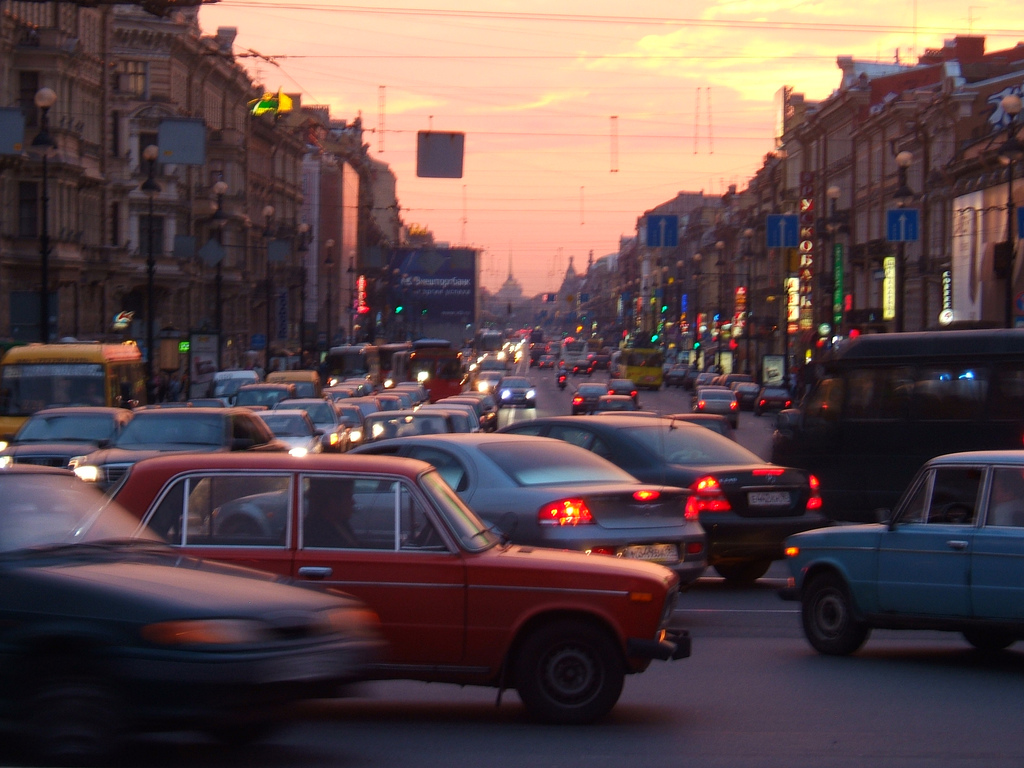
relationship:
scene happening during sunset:
[5, 3, 993, 760] [197, 5, 993, 289]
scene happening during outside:
[5, 3, 993, 760] [3, 3, 993, 758]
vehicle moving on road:
[70, 444, 695, 721] [5, 325, 993, 762]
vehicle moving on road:
[199, 424, 711, 595] [5, 325, 993, 762]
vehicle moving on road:
[495, 407, 828, 589] [5, 325, 993, 762]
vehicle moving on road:
[61, 400, 290, 504] [5, 325, 993, 762]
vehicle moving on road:
[247, 402, 328, 457] [5, 325, 993, 762]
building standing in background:
[3, 5, 312, 397] [1, 3, 989, 392]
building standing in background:
[294, 154, 362, 356] [1, 3, 989, 392]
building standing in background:
[301, 100, 405, 343] [1, 3, 989, 392]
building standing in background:
[770, 27, 993, 343] [1, 3, 989, 392]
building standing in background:
[636, 178, 738, 356] [1, 3, 989, 392]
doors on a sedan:
[136, 476, 467, 656] [58, 450, 692, 721]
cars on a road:
[30, 320, 1022, 763] [5, 325, 993, 762]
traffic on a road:
[0, 318, 1016, 748] [5, 325, 993, 762]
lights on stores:
[613, 249, 953, 377] [592, 201, 971, 411]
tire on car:
[505, 610, 629, 721] [89, 446, 692, 723]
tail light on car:
[536, 495, 595, 530] [203, 430, 707, 593]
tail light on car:
[680, 487, 704, 524] [203, 430, 707, 593]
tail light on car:
[804, 476, 824, 513] [490, 409, 828, 587]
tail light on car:
[687, 472, 731, 516] [477, 417, 823, 584]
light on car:
[144, 618, 255, 647] [6, 459, 383, 730]